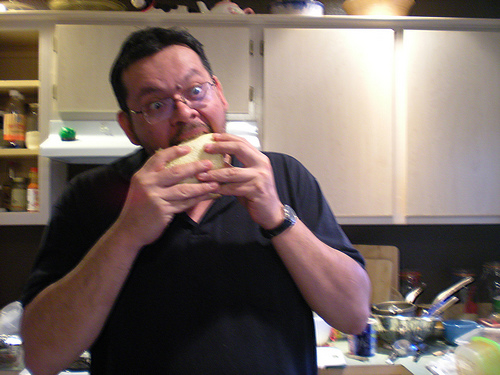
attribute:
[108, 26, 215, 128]
hair — black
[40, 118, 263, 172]
exhaust fan — white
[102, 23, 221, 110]
hair — short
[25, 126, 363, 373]
t-shirt — black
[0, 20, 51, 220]
cabinet — open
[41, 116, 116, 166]
ball — green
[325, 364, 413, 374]
boards — wooden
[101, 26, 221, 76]
hair — dark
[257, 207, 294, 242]
wristwatch — black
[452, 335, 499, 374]
container — plastic, empty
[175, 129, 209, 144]
mouth — open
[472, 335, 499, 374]
lid — green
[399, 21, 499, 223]
cabinet — white, wooden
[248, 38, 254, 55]
screws — small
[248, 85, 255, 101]
screws — small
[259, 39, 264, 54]
screws — small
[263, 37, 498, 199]
cabinets — white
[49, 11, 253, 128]
cabinets — white